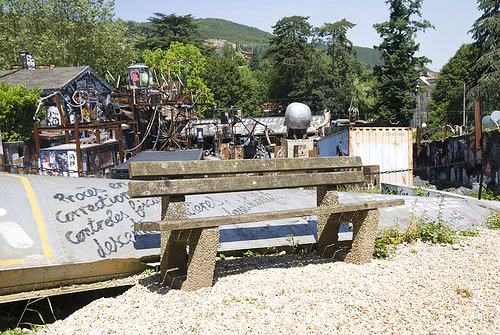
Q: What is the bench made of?
A: Wood.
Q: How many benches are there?
A: 1.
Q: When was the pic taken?
A: During the day.